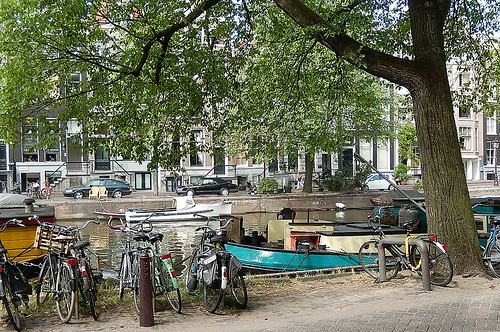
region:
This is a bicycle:
[25, 212, 77, 327]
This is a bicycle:
[73, 212, 118, 321]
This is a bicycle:
[105, 192, 160, 313]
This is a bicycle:
[150, 198, 195, 320]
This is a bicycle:
[178, 212, 225, 330]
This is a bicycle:
[225, 206, 255, 326]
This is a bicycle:
[344, 191, 468, 318]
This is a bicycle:
[0, 212, 33, 329]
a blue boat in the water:
[224, 238, 369, 265]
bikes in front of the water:
[6, 220, 250, 307]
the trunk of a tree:
[406, 18, 483, 269]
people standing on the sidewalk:
[11, 182, 71, 199]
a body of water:
[58, 210, 203, 267]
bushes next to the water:
[253, 176, 286, 185]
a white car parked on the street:
[358, 170, 398, 187]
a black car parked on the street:
[182, 176, 238, 196]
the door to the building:
[97, 138, 109, 169]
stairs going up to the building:
[42, 171, 69, 191]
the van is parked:
[69, 166, 149, 200]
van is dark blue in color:
[56, 173, 156, 202]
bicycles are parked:
[45, 232, 265, 299]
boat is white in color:
[163, 189, 226, 214]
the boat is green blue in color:
[262, 229, 337, 266]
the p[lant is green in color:
[268, 77, 366, 124]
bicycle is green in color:
[138, 228, 190, 317]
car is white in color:
[357, 162, 405, 198]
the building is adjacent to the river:
[27, 112, 127, 154]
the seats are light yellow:
[78, 182, 120, 199]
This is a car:
[55, 173, 142, 210]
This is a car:
[176, 165, 246, 204]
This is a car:
[178, 200, 227, 329]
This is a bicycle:
[182, 205, 223, 326]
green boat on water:
[184, 252, 359, 278]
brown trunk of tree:
[387, 47, 479, 284]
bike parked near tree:
[350, 202, 457, 294]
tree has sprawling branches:
[2, 4, 439, 207]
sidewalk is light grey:
[320, 296, 497, 328]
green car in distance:
[72, 181, 128, 198]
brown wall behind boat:
[243, 191, 353, 239]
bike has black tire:
[197, 252, 248, 297]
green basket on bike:
[158, 247, 178, 295]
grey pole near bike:
[379, 230, 426, 280]